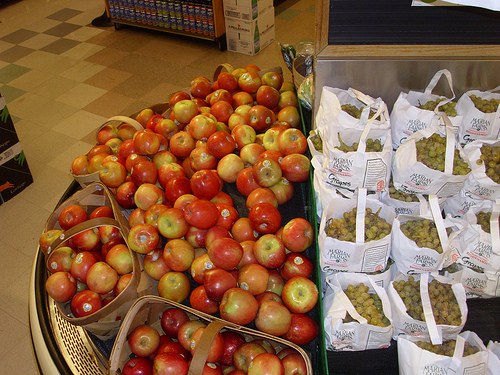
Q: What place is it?
A: It is a store.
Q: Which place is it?
A: It is a store.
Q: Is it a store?
A: Yes, it is a store.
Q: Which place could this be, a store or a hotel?
A: It is a store.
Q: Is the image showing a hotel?
A: No, the picture is showing a store.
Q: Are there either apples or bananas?
A: Yes, there is an apple.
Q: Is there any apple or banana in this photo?
A: Yes, there is an apple.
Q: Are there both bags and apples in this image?
A: Yes, there are both an apple and a bag.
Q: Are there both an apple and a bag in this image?
A: Yes, there are both an apple and a bag.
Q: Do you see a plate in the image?
A: No, there are no plates.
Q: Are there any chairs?
A: No, there are no chairs.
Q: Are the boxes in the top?
A: Yes, the boxes are in the top of the image.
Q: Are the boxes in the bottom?
A: No, the boxes are in the top of the image.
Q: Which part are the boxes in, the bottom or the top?
A: The boxes are in the top of the image.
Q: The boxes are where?
A: The boxes are on the floor.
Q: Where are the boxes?
A: The boxes are on the floor.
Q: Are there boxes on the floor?
A: Yes, there are boxes on the floor.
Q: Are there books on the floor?
A: No, there are boxes on the floor.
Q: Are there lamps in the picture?
A: No, there are no lamps.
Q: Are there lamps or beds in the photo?
A: No, there are no lamps or beds.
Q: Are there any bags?
A: Yes, there is a bag.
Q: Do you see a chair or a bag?
A: Yes, there is a bag.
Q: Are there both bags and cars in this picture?
A: No, there is a bag but no cars.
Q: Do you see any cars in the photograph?
A: No, there are no cars.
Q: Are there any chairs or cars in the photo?
A: No, there are no cars or chairs.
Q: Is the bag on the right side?
A: Yes, the bag is on the right of the image.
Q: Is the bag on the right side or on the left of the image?
A: The bag is on the right of the image.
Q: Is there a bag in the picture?
A: Yes, there is a bag.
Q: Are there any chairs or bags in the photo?
A: Yes, there is a bag.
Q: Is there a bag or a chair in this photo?
A: Yes, there is a bag.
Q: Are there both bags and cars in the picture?
A: No, there is a bag but no cars.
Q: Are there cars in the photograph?
A: No, there are no cars.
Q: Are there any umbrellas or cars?
A: No, there are no cars or umbrellas.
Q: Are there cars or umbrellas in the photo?
A: No, there are no cars or umbrellas.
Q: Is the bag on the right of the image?
A: Yes, the bag is on the right of the image.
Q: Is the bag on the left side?
A: No, the bag is on the right of the image.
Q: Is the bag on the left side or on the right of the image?
A: The bag is on the right of the image.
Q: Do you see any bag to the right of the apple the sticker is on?
A: Yes, there is a bag to the right of the apple.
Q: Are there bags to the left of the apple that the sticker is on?
A: No, the bag is to the right of the apple.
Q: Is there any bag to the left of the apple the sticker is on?
A: No, the bag is to the right of the apple.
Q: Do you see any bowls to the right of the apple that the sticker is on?
A: No, there is a bag to the right of the apple.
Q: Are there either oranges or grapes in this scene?
A: Yes, there are grapes.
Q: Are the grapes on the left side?
A: No, the grapes are on the right of the image.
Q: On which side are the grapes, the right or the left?
A: The grapes are on the right of the image.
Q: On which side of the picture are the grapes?
A: The grapes are on the right of the image.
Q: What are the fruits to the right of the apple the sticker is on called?
A: The fruits are grapes.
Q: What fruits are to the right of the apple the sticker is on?
A: The fruits are grapes.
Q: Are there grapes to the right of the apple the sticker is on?
A: Yes, there are grapes to the right of the apple.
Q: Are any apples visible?
A: Yes, there are apples.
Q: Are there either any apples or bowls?
A: Yes, there are apples.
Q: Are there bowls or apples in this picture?
A: Yes, there are apples.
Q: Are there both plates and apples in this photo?
A: No, there are apples but no plates.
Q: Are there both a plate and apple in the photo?
A: No, there are apples but no plates.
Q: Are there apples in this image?
A: Yes, there is an apple.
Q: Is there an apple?
A: Yes, there is an apple.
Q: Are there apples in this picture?
A: Yes, there is an apple.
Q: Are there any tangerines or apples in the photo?
A: Yes, there is an apple.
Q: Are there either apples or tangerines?
A: Yes, there is an apple.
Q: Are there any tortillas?
A: No, there are no tortillas.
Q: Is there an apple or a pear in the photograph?
A: Yes, there is an apple.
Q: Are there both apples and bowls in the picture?
A: No, there is an apple but no bowls.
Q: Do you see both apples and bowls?
A: No, there is an apple but no bowls.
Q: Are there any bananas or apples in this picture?
A: Yes, there is an apple.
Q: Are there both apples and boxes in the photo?
A: Yes, there are both an apple and a box.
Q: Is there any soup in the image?
A: No, there is no soup.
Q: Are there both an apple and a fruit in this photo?
A: Yes, there are both an apple and a fruit.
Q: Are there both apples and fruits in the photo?
A: Yes, there are both an apple and a fruit.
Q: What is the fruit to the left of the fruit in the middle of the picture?
A: The fruit is an apple.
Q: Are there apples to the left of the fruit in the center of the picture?
A: Yes, there is an apple to the left of the fruit.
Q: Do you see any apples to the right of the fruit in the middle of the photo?
A: No, the apple is to the left of the fruit.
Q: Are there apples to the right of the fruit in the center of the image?
A: No, the apple is to the left of the fruit.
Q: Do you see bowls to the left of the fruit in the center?
A: No, there is an apple to the left of the fruit.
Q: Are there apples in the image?
A: Yes, there is an apple.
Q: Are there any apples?
A: Yes, there is an apple.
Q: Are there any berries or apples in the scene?
A: Yes, there is an apple.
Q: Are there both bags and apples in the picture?
A: Yes, there are both an apple and a bag.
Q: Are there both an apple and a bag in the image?
A: Yes, there are both an apple and a bag.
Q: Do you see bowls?
A: No, there are no bowls.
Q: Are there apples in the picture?
A: Yes, there is an apple.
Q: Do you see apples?
A: Yes, there is an apple.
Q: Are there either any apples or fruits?
A: Yes, there is an apple.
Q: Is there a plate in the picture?
A: No, there are no plates.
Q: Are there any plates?
A: No, there are no plates.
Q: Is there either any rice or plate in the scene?
A: No, there are no plates or rice.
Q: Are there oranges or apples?
A: Yes, there is an apple.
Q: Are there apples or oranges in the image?
A: Yes, there is an apple.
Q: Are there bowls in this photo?
A: No, there are no bowls.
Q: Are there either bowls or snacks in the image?
A: No, there are no bowls or snacks.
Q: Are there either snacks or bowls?
A: No, there are no bowls or snacks.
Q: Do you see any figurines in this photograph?
A: No, there are no figurines.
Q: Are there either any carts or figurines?
A: No, there are no figurines or carts.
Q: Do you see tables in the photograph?
A: Yes, there is a table.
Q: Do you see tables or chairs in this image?
A: Yes, there is a table.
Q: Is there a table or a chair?
A: Yes, there is a table.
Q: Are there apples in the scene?
A: Yes, there are apples.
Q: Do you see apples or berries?
A: Yes, there are apples.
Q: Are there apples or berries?
A: Yes, there are apples.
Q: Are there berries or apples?
A: Yes, there are apples.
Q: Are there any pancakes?
A: No, there are no pancakes.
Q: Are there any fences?
A: No, there are no fences.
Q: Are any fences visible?
A: No, there are no fences.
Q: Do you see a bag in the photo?
A: Yes, there is a bag.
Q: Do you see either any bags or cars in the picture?
A: Yes, there is a bag.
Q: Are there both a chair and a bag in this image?
A: No, there is a bag but no chairs.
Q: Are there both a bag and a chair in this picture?
A: No, there is a bag but no chairs.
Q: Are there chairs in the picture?
A: No, there are no chairs.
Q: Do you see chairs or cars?
A: No, there are no chairs or cars.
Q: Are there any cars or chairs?
A: No, there are no chairs or cars.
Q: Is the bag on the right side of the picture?
A: Yes, the bag is on the right of the image.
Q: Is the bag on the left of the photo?
A: No, the bag is on the right of the image.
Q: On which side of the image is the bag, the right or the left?
A: The bag is on the right of the image.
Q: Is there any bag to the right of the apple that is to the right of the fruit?
A: Yes, there is a bag to the right of the apple.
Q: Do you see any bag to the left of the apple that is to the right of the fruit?
A: No, the bag is to the right of the apple.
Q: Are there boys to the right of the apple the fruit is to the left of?
A: No, there is a bag to the right of the apple.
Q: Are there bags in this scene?
A: Yes, there is a bag.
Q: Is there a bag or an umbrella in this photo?
A: Yes, there is a bag.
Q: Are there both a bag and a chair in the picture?
A: No, there is a bag but no chairs.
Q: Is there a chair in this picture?
A: No, there are no chairs.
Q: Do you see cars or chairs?
A: No, there are no chairs or cars.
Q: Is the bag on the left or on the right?
A: The bag is on the right of the image.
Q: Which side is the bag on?
A: The bag is on the right of the image.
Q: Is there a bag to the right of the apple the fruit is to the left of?
A: Yes, there is a bag to the right of the apple.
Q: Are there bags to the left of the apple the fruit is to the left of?
A: No, the bag is to the right of the apple.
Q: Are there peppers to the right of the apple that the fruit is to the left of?
A: No, there is a bag to the right of the apple.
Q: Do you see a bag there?
A: Yes, there is a bag.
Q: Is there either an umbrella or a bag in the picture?
A: Yes, there is a bag.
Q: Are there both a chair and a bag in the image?
A: No, there is a bag but no chairs.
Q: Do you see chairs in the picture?
A: No, there are no chairs.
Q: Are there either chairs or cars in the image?
A: No, there are no chairs or cars.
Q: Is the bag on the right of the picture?
A: Yes, the bag is on the right of the image.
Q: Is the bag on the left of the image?
A: No, the bag is on the right of the image.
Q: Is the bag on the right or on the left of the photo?
A: The bag is on the right of the image.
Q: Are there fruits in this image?
A: Yes, there is a fruit.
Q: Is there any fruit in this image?
A: Yes, there is a fruit.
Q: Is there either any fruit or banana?
A: Yes, there is a fruit.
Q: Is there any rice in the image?
A: No, there is no rice.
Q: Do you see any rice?
A: No, there is no rice.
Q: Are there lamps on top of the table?
A: No, there is a fruit on top of the table.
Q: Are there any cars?
A: No, there are no cars.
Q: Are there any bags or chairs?
A: Yes, there is a bag.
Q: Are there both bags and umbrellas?
A: No, there is a bag but no umbrellas.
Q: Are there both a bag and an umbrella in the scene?
A: No, there is a bag but no umbrellas.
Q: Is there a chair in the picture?
A: No, there are no chairs.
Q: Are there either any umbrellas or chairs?
A: No, there are no chairs or umbrellas.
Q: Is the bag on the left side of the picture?
A: No, the bag is on the right of the image.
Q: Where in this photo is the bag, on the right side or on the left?
A: The bag is on the right of the image.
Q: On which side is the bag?
A: The bag is on the right of the image.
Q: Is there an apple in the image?
A: Yes, there is an apple.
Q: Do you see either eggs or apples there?
A: Yes, there is an apple.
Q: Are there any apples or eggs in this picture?
A: Yes, there is an apple.